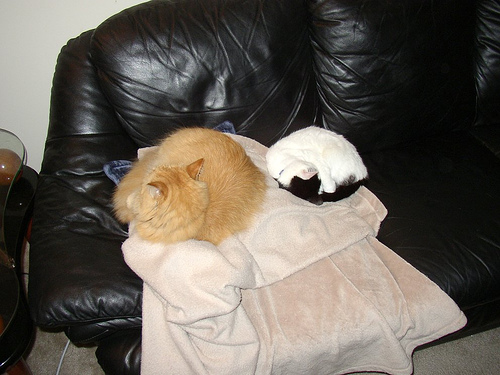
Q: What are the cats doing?
A: Napping.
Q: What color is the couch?
A: Black.